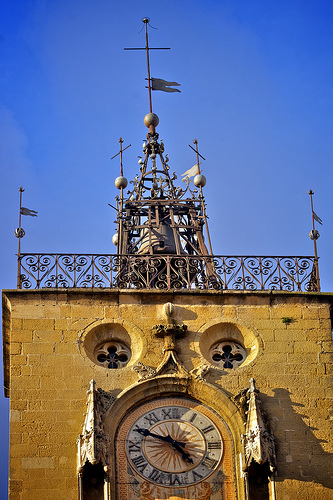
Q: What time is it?
A: 4:50.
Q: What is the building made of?
A: Brick.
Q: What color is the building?
A: Yellow.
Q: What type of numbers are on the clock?
A: Roman numerals.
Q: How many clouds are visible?
A: None.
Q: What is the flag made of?
A: Metal.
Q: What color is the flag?
A: Grey.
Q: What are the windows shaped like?
A: Circles.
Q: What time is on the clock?
A: 4:50.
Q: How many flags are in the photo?
A: Two.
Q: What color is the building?
A: Yellow.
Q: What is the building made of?
A: Brick.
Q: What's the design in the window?
A: Cross.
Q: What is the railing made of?
A: Metal.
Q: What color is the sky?
A: Blue.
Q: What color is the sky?
A: Blue.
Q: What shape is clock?
A: Circle.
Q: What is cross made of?
A: Metal.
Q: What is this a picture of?
A: A rooftop.